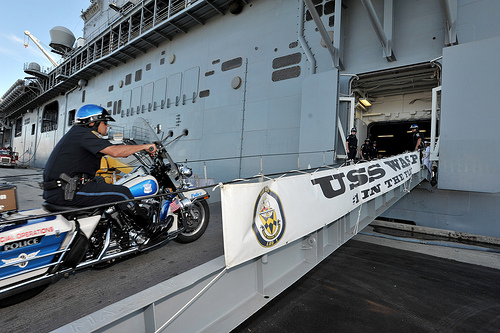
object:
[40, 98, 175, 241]
officer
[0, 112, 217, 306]
motorcycle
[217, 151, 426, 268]
banner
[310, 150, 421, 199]
uss wasp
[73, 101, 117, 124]
helmet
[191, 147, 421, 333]
ramp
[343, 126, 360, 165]
officer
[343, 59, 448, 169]
door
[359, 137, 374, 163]
officer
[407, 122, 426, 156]
officer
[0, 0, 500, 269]
boat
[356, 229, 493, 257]
water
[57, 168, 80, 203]
handgun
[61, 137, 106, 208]
side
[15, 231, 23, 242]
letters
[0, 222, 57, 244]
special operations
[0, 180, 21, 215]
box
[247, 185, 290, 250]
emblem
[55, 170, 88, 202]
holster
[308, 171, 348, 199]
letters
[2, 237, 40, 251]
police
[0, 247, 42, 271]
sign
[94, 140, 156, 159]
arm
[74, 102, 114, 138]
head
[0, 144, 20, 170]
truck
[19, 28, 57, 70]
crane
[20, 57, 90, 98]
building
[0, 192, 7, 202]
stickers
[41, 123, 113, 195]
shirt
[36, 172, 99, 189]
belt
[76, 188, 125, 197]
stripe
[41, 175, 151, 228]
pants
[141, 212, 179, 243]
boot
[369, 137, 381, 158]
people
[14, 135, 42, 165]
cables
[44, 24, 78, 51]
stations